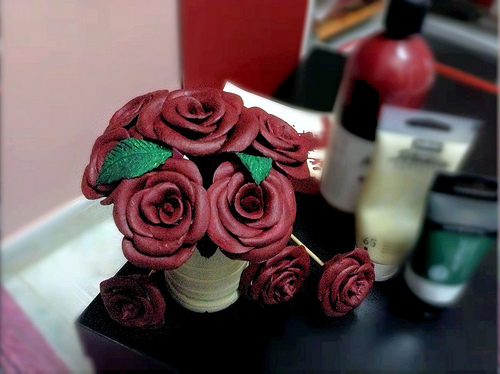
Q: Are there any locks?
A: No, there are no locks.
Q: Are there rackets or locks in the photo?
A: No, there are no locks or rackets.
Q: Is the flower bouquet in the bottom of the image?
A: Yes, the flower bouquet is in the bottom of the image.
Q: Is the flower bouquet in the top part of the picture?
A: No, the flower bouquet is in the bottom of the image.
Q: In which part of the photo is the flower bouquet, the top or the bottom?
A: The flower bouquet is in the bottom of the image.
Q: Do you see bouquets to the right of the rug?
A: Yes, there is a bouquet to the right of the rug.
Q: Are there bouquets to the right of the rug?
A: Yes, there is a bouquet to the right of the rug.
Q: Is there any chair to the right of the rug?
A: No, there is a bouquet to the right of the rug.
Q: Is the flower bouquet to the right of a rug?
A: Yes, the flower bouquet is to the right of a rug.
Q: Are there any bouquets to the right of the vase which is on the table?
A: Yes, there is a bouquet to the right of the vase.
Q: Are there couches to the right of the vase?
A: No, there is a bouquet to the right of the vase.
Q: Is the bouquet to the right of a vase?
A: Yes, the bouquet is to the right of a vase.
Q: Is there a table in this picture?
A: Yes, there is a table.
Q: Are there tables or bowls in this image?
A: Yes, there is a table.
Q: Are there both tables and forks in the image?
A: No, there is a table but no forks.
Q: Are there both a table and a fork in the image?
A: No, there is a table but no forks.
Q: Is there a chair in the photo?
A: No, there are no chairs.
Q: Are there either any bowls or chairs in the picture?
A: No, there are no chairs or bowls.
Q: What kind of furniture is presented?
A: The furniture is a table.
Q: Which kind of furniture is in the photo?
A: The furniture is a table.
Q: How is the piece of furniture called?
A: The piece of furniture is a table.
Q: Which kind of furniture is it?
A: The piece of furniture is a table.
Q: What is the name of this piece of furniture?
A: This is a table.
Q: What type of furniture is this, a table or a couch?
A: This is a table.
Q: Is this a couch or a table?
A: This is a table.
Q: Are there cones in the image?
A: No, there are no cones.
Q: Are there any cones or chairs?
A: No, there are no cones or chairs.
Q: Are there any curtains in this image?
A: No, there are no curtains.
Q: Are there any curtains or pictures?
A: No, there are no curtains or pictures.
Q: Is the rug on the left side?
A: Yes, the rug is on the left of the image.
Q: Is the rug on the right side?
A: No, the rug is on the left of the image.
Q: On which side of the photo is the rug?
A: The rug is on the left of the image.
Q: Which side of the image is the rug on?
A: The rug is on the left of the image.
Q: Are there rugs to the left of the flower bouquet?
A: Yes, there is a rug to the left of the flower bouquet.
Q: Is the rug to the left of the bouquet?
A: Yes, the rug is to the left of the bouquet.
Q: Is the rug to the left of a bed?
A: No, the rug is to the left of the bouquet.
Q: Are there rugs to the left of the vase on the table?
A: Yes, there is a rug to the left of the vase.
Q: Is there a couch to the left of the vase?
A: No, there is a rug to the left of the vase.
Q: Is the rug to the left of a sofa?
A: No, the rug is to the left of the vase.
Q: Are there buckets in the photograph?
A: No, there are no buckets.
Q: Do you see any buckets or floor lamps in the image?
A: No, there are no buckets or floor lamps.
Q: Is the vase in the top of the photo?
A: No, the vase is in the bottom of the image.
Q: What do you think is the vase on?
A: The vase is on the table.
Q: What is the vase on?
A: The vase is on the table.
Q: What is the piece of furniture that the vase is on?
A: The piece of furniture is a table.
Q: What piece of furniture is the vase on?
A: The vase is on the table.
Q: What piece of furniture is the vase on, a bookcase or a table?
A: The vase is on a table.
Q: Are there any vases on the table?
A: Yes, there is a vase on the table.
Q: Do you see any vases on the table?
A: Yes, there is a vase on the table.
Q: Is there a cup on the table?
A: No, there is a vase on the table.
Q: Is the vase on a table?
A: Yes, the vase is on a table.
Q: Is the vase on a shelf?
A: No, the vase is on a table.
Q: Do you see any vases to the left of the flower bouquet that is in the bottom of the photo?
A: Yes, there is a vase to the left of the flower bouquet.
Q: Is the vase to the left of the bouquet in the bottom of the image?
A: Yes, the vase is to the left of the flower bouquet.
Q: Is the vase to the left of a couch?
A: No, the vase is to the left of the flower bouquet.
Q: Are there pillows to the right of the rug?
A: No, there is a vase to the right of the rug.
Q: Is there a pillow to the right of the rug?
A: No, there is a vase to the right of the rug.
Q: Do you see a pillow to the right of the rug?
A: No, there is a vase to the right of the rug.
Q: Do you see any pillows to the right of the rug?
A: No, there is a vase to the right of the rug.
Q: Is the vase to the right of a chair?
A: No, the vase is to the right of the rug.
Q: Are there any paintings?
A: No, there are no paintings.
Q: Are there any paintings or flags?
A: No, there are no paintings or flags.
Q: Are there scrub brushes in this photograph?
A: No, there are no scrub brushes.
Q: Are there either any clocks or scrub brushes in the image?
A: No, there are no scrub brushes or clocks.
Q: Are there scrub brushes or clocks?
A: No, there are no scrub brushes or clocks.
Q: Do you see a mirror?
A: No, there are no mirrors.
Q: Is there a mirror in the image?
A: No, there are no mirrors.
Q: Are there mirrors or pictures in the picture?
A: No, there are no mirrors or pictures.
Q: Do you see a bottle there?
A: Yes, there is a bottle.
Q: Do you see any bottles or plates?
A: Yes, there is a bottle.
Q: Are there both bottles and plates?
A: No, there is a bottle but no plates.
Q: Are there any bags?
A: No, there are no bags.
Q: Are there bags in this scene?
A: No, there are no bags.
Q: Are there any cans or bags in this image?
A: No, there are no bags or cans.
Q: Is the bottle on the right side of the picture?
A: Yes, the bottle is on the right of the image.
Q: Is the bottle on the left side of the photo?
A: No, the bottle is on the right of the image.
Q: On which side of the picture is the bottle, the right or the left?
A: The bottle is on the right of the image.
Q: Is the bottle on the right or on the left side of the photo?
A: The bottle is on the right of the image.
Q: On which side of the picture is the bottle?
A: The bottle is on the right of the image.